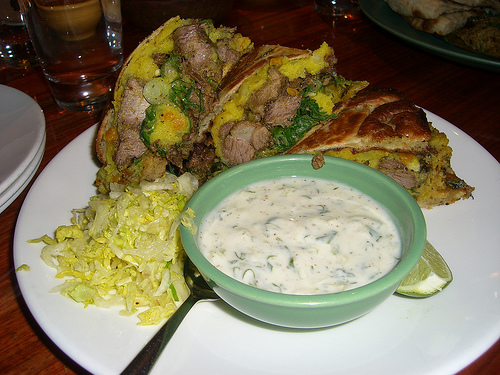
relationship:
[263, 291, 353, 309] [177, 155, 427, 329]
edge of dish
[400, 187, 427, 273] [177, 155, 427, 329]
edge of dish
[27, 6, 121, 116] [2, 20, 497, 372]
glass on table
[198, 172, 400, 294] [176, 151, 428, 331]
soup in bowl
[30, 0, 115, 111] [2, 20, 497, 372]
glass on table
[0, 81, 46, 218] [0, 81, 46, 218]
dish on top of dish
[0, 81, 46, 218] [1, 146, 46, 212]
dish on top of plate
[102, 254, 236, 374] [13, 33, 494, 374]
spoon on plate